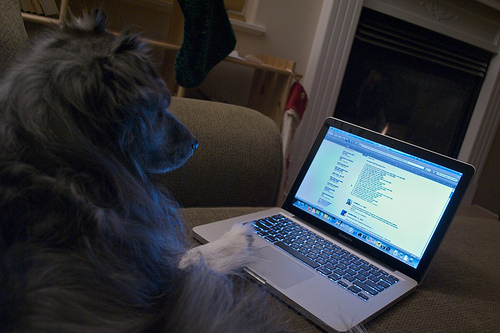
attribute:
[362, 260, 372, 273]
keyboard button — black, white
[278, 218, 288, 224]
button — white, black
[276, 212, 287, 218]
button — white, black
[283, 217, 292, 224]
button — white, black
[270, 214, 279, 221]
button — white, black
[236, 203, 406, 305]
keyboard — illuminated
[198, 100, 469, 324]
laptop — turned on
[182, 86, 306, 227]
couch — brown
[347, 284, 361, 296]
button — black, white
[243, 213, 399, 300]
keyboard — white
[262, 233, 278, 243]
button — black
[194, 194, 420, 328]
base — silver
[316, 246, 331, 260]
button — black, white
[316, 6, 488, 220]
fireplace — pictured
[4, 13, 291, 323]
dog — dark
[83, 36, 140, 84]
dog — hairy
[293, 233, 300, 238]
button — black, white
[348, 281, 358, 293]
button — black, white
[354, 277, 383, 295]
button — white, black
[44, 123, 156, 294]
fur — fluffy